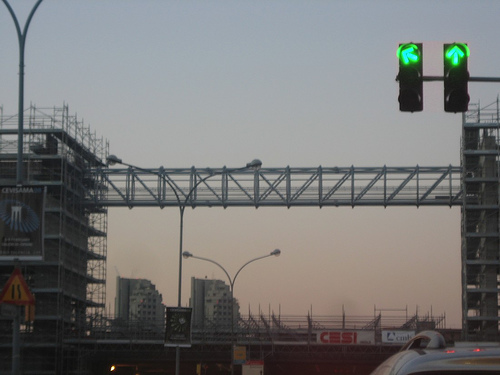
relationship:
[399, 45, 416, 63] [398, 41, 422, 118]
green arrow on light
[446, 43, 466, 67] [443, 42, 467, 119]
green arrow on light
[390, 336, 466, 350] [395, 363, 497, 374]
top of vehicle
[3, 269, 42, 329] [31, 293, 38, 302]
sign has red border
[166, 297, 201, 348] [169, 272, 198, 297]
sign on pole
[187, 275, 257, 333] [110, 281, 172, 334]
building next to building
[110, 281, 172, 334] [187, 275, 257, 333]
building next to building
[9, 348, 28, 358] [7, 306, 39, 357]
part of post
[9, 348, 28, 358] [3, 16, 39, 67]
part of lamp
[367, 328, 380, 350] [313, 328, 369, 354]
edge of sign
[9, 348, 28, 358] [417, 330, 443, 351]
part of handle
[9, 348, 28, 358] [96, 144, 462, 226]
part of walkway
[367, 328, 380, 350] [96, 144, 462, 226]
edge of walkway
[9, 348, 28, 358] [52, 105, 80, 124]
part of metal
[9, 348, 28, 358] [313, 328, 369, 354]
part of sign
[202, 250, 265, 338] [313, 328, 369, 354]
street light with sign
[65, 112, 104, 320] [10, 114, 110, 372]
scaffold around building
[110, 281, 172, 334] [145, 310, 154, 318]
building has several windows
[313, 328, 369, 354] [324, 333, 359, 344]
sign with letters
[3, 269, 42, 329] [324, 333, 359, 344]
sign with letters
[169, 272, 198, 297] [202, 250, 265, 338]
pole with street light